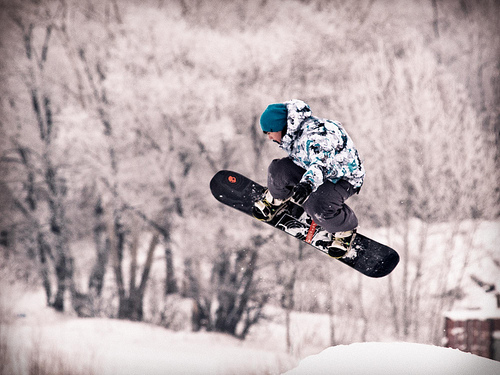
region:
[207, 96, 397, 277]
Man on snowboard in air.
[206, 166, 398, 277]
Snowboard with red decorations.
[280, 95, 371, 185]
Green designs on jacket.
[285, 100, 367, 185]
Black designs on jacket.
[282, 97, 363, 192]
Long sleeves on jacket.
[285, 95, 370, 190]
Multicolored jacket with hood.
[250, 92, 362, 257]
Man wearing teal colored hat.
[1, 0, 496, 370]
Snow on top of tall trees.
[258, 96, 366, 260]
Man wearing black glove on left hand.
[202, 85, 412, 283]
The man is currently snowboarding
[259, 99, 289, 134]
Blue cap on his head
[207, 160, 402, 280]
Black and orange snowboard being ridden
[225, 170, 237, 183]
Orange logo on the front of the board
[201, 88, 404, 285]
Man in air after hitting a ramp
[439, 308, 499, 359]
Brick fence in background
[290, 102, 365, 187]
White, black and blue hoodie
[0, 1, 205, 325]
Patch of trees in the background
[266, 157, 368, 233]
Gray pants being worn by the snowboarder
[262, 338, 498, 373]
Mound of snow under the snowboarder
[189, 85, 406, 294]
A person in the air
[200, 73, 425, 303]
A person snowboarding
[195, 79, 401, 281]
a person on a snowboard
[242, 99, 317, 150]
A person wearing a knit cap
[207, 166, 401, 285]
black snowboard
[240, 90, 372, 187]
A person wearing a white sweater with prints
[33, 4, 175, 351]
trees covered with snow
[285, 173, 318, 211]
hand wearing a black glove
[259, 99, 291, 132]
blue hat on snowboarder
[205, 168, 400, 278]
a black snowboard with white and red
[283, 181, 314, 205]
the left hand with black glove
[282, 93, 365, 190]
coat with black green and white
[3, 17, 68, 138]
snow filled trees in the forest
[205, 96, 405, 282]
snowboarder is in the air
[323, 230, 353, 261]
black shoe on the snowboarder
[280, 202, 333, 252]
white and black designs on snowboard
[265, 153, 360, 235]
black pants on the snowboarder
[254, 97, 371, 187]
man with blue had and winter coat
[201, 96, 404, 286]
snowboarder in midair.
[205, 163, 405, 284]
Black snowboard under the person.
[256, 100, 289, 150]
Hat on the person.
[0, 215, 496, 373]
snow covering the ground.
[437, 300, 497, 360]
building in the background.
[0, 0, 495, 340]
Trees in the background.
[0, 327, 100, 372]
Brown brush on the ground.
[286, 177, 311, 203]
Black gloves on the hand.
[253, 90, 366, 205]
black, white, blue, and gray jacket.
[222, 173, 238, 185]
Red emblem on snowboard.